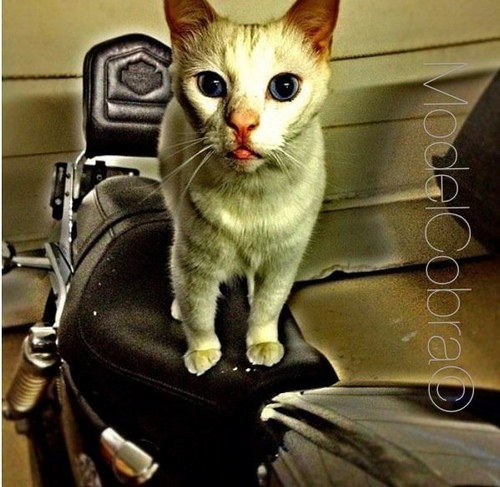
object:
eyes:
[193, 64, 228, 97]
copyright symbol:
[426, 362, 476, 415]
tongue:
[232, 148, 250, 157]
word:
[411, 54, 480, 368]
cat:
[151, 2, 340, 381]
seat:
[61, 172, 337, 482]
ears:
[161, 1, 224, 45]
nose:
[224, 106, 262, 132]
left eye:
[262, 68, 312, 108]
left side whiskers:
[267, 140, 336, 195]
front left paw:
[243, 337, 284, 366]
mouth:
[221, 145, 264, 162]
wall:
[6, 5, 493, 270]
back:
[78, 34, 170, 151]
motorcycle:
[9, 28, 497, 486]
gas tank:
[43, 152, 154, 216]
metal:
[42, 157, 82, 288]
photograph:
[0, 0, 479, 471]